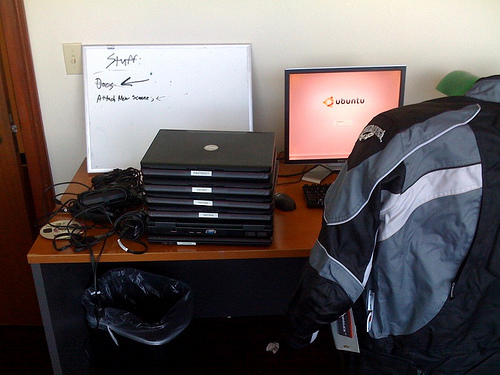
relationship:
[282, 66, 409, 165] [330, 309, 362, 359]
monitor to a computer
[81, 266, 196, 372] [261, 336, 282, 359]
can for trash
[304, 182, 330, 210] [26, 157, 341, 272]
keyboard on top of desk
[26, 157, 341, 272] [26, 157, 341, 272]
desk has a top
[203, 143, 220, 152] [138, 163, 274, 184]
decal on top of laptop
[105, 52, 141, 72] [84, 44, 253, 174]
stuff written on dry erase board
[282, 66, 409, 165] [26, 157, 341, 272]
black monitor on top of a desk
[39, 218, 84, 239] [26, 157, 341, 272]
cd on top of a desk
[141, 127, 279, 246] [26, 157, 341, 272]
laptops on top of a desk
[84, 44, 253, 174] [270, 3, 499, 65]
board propped against wall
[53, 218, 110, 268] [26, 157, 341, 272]
wire on top of desk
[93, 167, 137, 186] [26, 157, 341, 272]
wire on top of desk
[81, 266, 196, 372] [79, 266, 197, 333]
trash can has liner